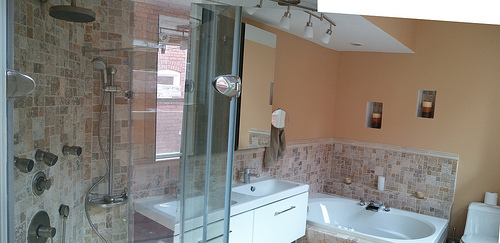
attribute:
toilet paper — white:
[481, 191, 499, 205]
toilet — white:
[461, 208, 499, 241]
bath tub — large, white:
[303, 199, 442, 242]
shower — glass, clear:
[1, 1, 224, 241]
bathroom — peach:
[4, 2, 497, 238]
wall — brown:
[243, 24, 496, 211]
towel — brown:
[267, 123, 290, 167]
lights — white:
[239, 3, 341, 45]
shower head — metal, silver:
[94, 53, 122, 96]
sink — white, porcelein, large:
[239, 184, 297, 200]